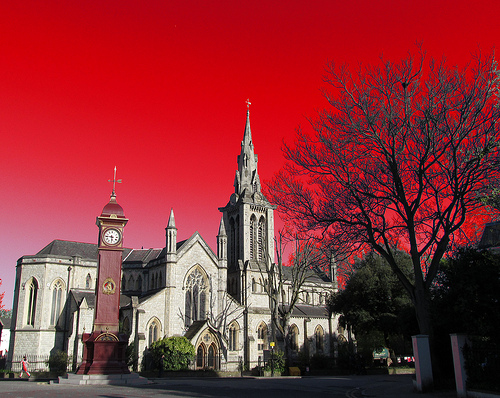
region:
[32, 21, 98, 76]
white clouds in red sky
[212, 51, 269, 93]
white clouds in red sky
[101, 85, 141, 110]
white clouds in red sky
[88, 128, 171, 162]
white clouds in red sky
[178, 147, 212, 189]
white clouds in red sky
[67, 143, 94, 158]
white clouds in red sky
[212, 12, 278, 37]
white clouds in red sky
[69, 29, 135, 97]
white clouds in red sky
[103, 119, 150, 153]
white clouds in red sky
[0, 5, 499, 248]
red sky above church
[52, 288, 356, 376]
shadows on the church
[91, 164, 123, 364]
red clock tower on church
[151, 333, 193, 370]
bush beside the church door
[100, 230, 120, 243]
white clockface on clock tower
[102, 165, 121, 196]
cross on top of clock tower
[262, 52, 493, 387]
tree with any leaves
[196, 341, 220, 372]
double doors to the church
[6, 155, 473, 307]
red sky fading to pink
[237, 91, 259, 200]
steeple of the church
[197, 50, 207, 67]
white clouds in red sky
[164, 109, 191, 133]
white clouds in red sky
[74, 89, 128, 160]
white clouds in red sky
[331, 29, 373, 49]
white clouds in red sky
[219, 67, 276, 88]
white clouds in red sky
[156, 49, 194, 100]
white clouds in red sky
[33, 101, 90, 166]
white clouds in red sky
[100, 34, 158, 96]
white clouds in red sky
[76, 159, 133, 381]
a very tall clock tower with a cros on top of it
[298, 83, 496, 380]
a very large tree with no leaves on it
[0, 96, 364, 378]
a very large church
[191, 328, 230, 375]
the church entrance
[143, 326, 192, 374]
some very large bushes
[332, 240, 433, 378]
some large trees with leaves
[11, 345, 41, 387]
a person walking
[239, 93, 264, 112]
a cross on top of the church tower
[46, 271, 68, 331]
a very tall window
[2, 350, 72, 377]
a metal fence around the church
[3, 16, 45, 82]
white clouds in red sky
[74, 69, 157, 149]
white clouds in red sky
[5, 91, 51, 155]
white clouds in red sky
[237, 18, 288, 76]
white clouds in red sky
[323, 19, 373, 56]
white clouds in red sky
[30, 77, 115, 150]
white clouds in red sky